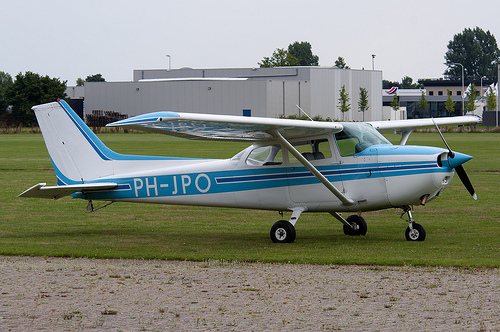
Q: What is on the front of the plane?
A: Propeller.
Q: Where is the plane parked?
A: On the grass.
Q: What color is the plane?
A: Blue and white.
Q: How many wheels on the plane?
A: Three.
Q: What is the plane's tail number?
A: PH-JPO.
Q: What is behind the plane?
A: Building.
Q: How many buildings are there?
A: Two.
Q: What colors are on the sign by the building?
A: Red, white and blue.